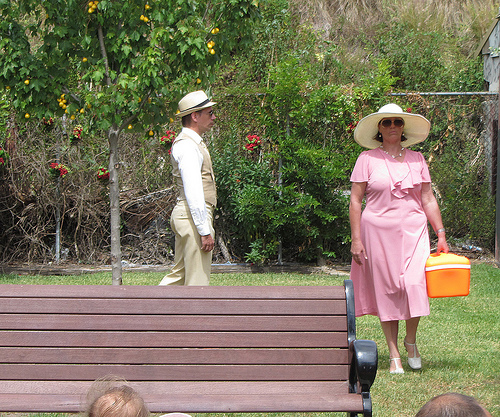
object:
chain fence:
[429, 94, 493, 204]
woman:
[342, 96, 444, 381]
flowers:
[46, 157, 73, 178]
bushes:
[39, 105, 165, 211]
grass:
[3, 262, 498, 415]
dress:
[349, 147, 434, 319]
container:
[418, 235, 470, 298]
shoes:
[388, 339, 425, 376]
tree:
[2, 2, 249, 276]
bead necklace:
[384, 148, 415, 183]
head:
[376, 120, 406, 147]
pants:
[155, 200, 214, 287]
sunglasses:
[377, 115, 404, 128]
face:
[375, 113, 406, 141]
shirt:
[170, 132, 211, 210]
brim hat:
[353, 103, 431, 147]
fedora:
[173, 89, 219, 116]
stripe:
[181, 97, 211, 112]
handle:
[431, 239, 446, 262]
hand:
[436, 240, 448, 254]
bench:
[0, 273, 379, 417]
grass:
[403, 320, 486, 374]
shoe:
[399, 332, 427, 368]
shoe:
[380, 345, 405, 374]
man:
[156, 89, 219, 289]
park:
[0, 0, 497, 415]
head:
[177, 90, 220, 131]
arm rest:
[342, 280, 378, 410]